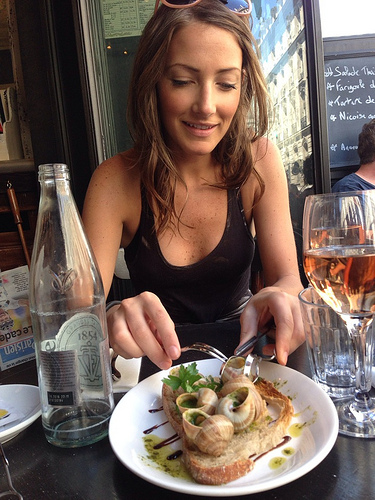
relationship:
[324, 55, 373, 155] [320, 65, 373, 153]
chalk board with writing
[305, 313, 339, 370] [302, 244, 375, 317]
glass with liquid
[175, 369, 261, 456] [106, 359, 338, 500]
escargot on plate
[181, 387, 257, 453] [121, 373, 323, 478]
escargo on bread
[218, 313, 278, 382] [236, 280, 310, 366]
silver utensil in hand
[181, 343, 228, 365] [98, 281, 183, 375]
fork in hand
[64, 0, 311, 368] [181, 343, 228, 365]
woman holding fork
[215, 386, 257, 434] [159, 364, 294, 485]
escargot on toast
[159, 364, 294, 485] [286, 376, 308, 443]
toast on plate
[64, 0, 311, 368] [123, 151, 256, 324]
woman wearing shirt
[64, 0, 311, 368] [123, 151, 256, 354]
woman in shirt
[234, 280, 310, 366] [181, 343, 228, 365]
hand hold fork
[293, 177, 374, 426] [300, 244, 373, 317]
glass hold liquid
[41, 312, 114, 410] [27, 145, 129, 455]
label on bottle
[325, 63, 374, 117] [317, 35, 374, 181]
menu on chalkboard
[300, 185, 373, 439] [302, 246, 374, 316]
glass with beverage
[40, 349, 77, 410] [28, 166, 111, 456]
label on bottle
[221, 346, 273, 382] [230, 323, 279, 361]
opener with handle